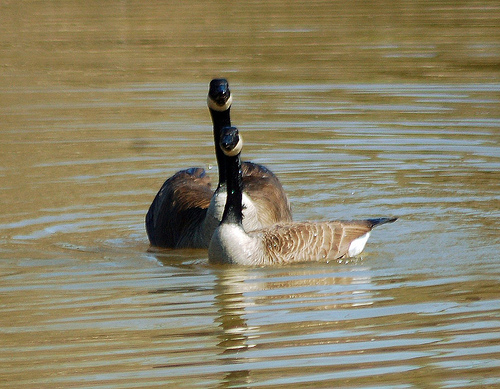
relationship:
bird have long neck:
[144, 78, 295, 250] [202, 141, 263, 231]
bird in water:
[206, 127, 399, 265] [249, 96, 461, 314]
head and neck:
[203, 71, 235, 114] [200, 120, 241, 178]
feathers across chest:
[215, 216, 253, 262] [206, 222, 253, 266]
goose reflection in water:
[211, 266, 248, 387] [14, 11, 494, 376]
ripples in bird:
[288, 278, 391, 351] [206, 127, 399, 265]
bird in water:
[206, 127, 399, 265] [14, 11, 494, 376]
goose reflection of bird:
[211, 266, 248, 387] [206, 127, 399, 265]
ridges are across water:
[14, 191, 498, 386] [14, 11, 494, 376]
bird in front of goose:
[206, 127, 399, 265] [162, 77, 237, 253]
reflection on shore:
[72, 70, 198, 107] [8, 2, 498, 382]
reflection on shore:
[297, 80, 476, 100] [8, 2, 498, 382]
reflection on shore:
[412, 223, 489, 277] [8, 2, 498, 382]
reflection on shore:
[65, 310, 253, 366] [8, 2, 498, 382]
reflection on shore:
[338, 315, 453, 369] [8, 2, 498, 382]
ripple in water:
[0, 267, 499, 343] [14, 11, 494, 376]